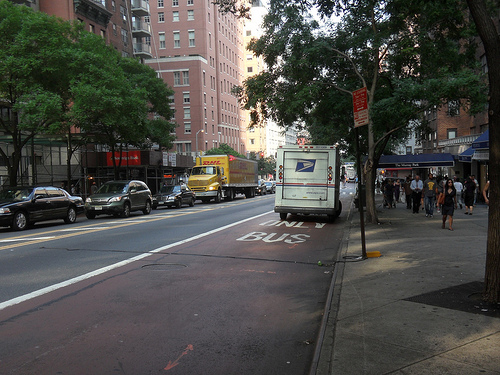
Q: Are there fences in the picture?
A: No, there are no fences.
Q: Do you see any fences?
A: No, there are no fences.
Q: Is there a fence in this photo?
A: No, there are no fences.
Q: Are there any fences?
A: No, there are no fences.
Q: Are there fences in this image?
A: No, there are no fences.